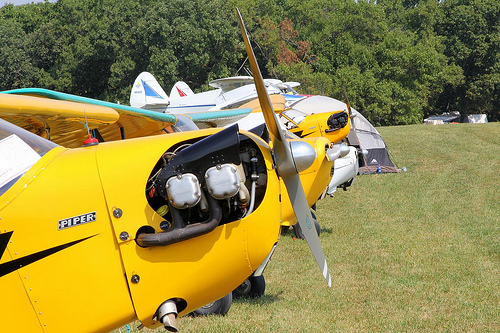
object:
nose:
[289, 140, 318, 174]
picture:
[0, 0, 499, 332]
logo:
[57, 211, 97, 231]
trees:
[0, 0, 64, 92]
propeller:
[231, 5, 335, 289]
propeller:
[341, 85, 362, 147]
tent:
[276, 93, 409, 177]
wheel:
[231, 272, 264, 300]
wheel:
[189, 291, 232, 316]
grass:
[168, 119, 497, 331]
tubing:
[135, 192, 223, 247]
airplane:
[0, 6, 335, 332]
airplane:
[0, 87, 370, 241]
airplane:
[129, 70, 302, 116]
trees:
[361, 25, 467, 126]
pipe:
[155, 298, 180, 332]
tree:
[251, 10, 314, 73]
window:
[0, 116, 69, 210]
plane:
[0, 84, 352, 320]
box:
[166, 173, 203, 210]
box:
[204, 163, 240, 200]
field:
[112, 122, 499, 332]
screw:
[131, 274, 141, 284]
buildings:
[423, 113, 470, 125]